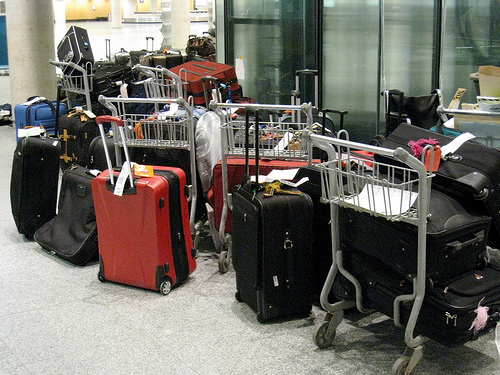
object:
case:
[89, 115, 200, 293]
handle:
[95, 114, 136, 187]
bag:
[327, 174, 488, 285]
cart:
[306, 130, 438, 374]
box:
[477, 64, 499, 99]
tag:
[133, 163, 156, 177]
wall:
[215, 0, 499, 127]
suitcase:
[13, 95, 68, 139]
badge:
[113, 160, 132, 196]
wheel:
[313, 321, 336, 349]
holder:
[243, 104, 262, 190]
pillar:
[3, 0, 59, 128]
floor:
[0, 127, 499, 374]